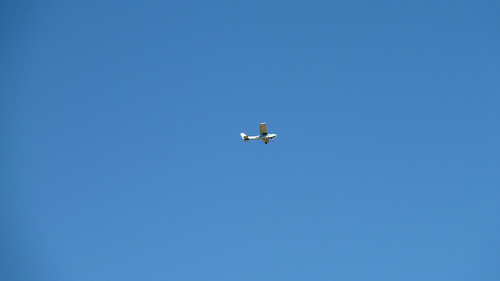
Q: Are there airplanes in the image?
A: Yes, there is an airplane.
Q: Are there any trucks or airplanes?
A: Yes, there is an airplane.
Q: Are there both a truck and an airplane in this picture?
A: No, there is an airplane but no trucks.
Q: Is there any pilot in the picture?
A: No, there are no pilots.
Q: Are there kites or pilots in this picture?
A: No, there are no pilots or kites.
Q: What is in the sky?
A: The airplane is in the sky.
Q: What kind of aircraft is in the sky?
A: The aircraft is an airplane.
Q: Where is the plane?
A: The plane is in the sky.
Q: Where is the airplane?
A: The plane is in the sky.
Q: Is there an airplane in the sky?
A: Yes, there is an airplane in the sky.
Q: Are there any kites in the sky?
A: No, there is an airplane in the sky.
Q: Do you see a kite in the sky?
A: No, there is an airplane in the sky.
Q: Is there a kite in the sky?
A: No, there is an airplane in the sky.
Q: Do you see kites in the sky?
A: No, there is an airplane in the sky.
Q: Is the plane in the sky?
A: Yes, the plane is in the sky.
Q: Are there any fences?
A: No, there are no fences.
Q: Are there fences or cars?
A: No, there are no fences or cars.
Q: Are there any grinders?
A: No, there are no grinders.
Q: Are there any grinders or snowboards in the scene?
A: No, there are no grinders or snowboards.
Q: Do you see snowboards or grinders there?
A: No, there are no grinders or snowboards.